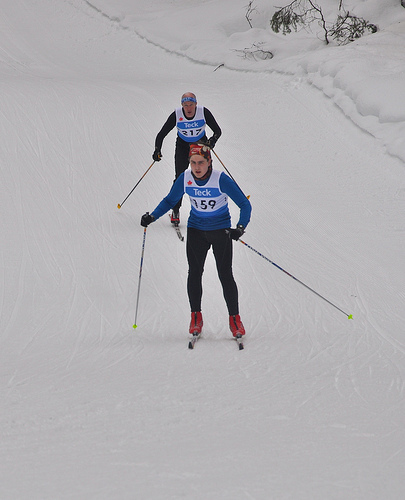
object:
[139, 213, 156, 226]
glove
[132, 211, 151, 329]
pole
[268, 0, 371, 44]
tree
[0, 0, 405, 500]
snow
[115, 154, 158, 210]
pole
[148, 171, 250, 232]
shirt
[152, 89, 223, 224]
competitors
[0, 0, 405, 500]
slope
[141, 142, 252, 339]
competitor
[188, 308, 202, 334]
boot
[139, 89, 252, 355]
sport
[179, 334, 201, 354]
tip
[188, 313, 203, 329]
part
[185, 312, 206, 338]
shoes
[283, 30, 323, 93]
part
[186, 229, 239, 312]
trouser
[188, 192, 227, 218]
bib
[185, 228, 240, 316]
pants